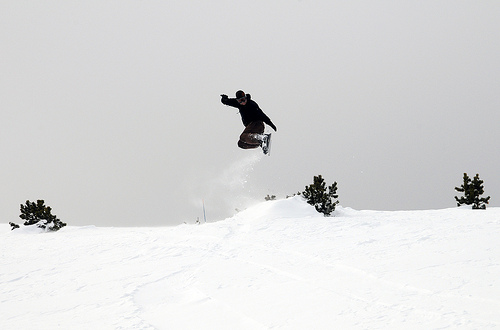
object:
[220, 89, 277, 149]
man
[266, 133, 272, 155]
board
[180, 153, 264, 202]
snow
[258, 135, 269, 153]
boots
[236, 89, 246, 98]
cap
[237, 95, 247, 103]
googles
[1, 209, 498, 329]
hill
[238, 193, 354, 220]
snow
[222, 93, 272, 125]
jacket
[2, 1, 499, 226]
sky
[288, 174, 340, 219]
bush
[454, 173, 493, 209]
bush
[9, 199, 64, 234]
bush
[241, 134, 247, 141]
knee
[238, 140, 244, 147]
knee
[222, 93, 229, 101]
hand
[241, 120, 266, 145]
leg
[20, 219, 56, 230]
snow